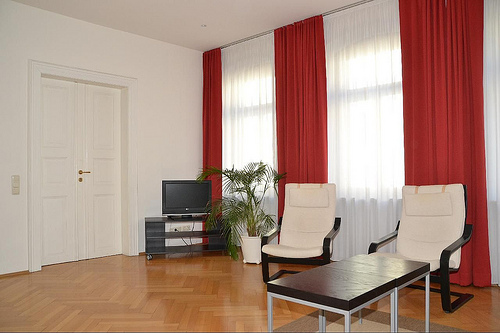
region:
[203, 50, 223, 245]
red long window curtain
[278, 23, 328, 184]
red long window curtain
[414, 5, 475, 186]
red long window curtain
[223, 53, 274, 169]
white long window curtain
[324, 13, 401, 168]
white long window curtain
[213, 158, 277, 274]
house plant in a white pot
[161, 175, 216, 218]
tv is off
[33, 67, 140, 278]
doors with bronze knobs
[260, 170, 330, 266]
white chair with black arm rest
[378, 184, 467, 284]
white chair with black arm rest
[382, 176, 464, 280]
white chair in room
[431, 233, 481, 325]
black handle of chair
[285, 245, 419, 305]
black top to table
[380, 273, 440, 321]
silver legs to table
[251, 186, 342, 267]
white top to chair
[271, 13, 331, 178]
red curtains on wall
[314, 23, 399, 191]
white curtains on windows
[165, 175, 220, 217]
small tv on stand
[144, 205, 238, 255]
black tv stand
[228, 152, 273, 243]
small green bush in planter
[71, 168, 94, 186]
FANCY HANDLE OF DOOR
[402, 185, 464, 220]
BACK OF WHITE CHAIR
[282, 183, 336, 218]
BACK OF WHITE CHAIR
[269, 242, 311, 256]
SEAT OF WHITE CHAIR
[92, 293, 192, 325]
BROWN WOODEN FLOOR OF ROOM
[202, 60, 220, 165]
PART OF LONG RED DRAPE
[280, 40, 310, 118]
PART OF LONG RED DRAPE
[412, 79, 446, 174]
PART OF LONG RED DRAPE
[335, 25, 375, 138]
LONG SHEER DRAPERY CURTAIN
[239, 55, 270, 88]
PART OF LONG SHEER CURTAIN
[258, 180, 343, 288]
a white wooden chair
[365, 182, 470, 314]
a white wooden chair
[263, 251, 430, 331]
a white wooden table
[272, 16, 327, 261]
a long red curtain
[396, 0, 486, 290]
a long red curtain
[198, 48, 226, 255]
a long red curtain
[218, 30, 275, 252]
a long white curtain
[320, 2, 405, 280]
a long white curtain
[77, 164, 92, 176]
a gold door handle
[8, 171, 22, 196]
a light switch on a wall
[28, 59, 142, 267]
double doors are leading into the room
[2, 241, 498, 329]
the wood floor has a herringbone design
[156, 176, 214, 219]
a flat screen tv is in the corner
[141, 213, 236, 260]
an electronics cabinet is under the tv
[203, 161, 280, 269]
a potted palm is next to the tv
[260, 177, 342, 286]
the chair has white upholstery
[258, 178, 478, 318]
two chairs are in the room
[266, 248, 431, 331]
a table with a dark top is in the room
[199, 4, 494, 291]
the red curtains are hanging from the ceiling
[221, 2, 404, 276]
white curtains are on the windows